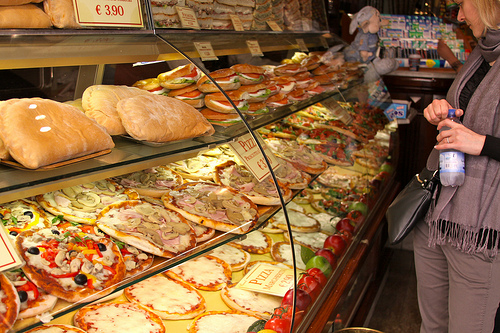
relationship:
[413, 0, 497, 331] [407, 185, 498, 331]
woman wearing gray pants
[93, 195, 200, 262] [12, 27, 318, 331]
pizza in a case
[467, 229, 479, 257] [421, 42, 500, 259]
fringe on scarf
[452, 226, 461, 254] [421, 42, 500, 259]
fringe on scarf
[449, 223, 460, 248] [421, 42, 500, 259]
fringe on scarf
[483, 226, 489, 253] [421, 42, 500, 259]
fringe on scarf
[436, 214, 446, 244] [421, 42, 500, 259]
fringe on scarf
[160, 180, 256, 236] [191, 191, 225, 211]
pizza with toppings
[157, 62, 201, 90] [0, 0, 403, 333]
sandwich in display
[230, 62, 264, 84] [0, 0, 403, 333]
sandwich in display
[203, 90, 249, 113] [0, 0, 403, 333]
sandwich in display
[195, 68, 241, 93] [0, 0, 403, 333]
sandwich in display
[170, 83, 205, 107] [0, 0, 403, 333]
sandwich in display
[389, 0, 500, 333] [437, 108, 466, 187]
woman holding bottle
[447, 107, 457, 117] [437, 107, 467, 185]
cap on bottle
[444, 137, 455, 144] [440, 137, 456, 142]
band around finger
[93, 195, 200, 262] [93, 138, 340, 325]
pizza behind glass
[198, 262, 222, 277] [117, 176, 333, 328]
cheese behind glass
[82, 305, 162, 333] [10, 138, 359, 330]
pizza behind glass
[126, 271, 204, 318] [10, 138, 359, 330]
pizza behind glass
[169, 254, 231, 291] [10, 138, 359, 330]
pizza behind glass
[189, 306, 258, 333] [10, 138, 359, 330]
pizza behind glass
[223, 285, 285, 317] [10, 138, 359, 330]
pizza behind glass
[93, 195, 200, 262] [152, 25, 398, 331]
pizza behind glass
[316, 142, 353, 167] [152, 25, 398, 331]
cheese pizza behind glass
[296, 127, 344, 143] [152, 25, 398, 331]
cheese pizza behind glass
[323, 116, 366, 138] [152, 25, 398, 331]
cheese pizza behind glass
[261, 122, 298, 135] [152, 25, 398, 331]
cheese pizza behind glass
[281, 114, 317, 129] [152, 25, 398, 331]
cheese pizza behind glass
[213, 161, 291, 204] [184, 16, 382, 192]
pizza behind glass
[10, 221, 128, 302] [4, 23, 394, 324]
pizza in shelf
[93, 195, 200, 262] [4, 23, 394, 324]
pizza in shelf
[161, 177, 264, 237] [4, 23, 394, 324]
pizza in shelf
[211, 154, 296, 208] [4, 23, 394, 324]
pizza in shelf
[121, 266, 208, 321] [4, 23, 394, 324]
pizza in shelf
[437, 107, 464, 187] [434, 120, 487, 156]
bottle in hand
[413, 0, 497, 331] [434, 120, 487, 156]
woman has hand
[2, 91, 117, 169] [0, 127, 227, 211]
calzone on shelf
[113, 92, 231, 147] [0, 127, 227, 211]
calzone on shelf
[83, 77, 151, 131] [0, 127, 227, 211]
calzone on shelf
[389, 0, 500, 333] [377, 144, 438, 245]
woman has purse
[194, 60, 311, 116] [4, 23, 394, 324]
sandwiches on shelf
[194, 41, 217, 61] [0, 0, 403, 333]
sign on display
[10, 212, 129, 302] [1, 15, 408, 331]
pizza in case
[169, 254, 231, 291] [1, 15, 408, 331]
pizza in case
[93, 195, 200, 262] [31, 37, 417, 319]
pizza in case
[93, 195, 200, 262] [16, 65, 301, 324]
pizza in case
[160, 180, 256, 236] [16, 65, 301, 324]
pizza in case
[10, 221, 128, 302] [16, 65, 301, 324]
pizza in case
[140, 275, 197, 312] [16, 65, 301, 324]
pizza in case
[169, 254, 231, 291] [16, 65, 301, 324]
pizza in case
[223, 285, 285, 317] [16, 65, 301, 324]
pizza in case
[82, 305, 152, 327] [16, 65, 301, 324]
pizza in case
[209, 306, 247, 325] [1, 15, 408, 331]
pizza in case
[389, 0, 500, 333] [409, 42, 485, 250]
woman wearing scarf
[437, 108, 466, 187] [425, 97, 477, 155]
bottle in hands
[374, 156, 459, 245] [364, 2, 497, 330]
purse carried by woman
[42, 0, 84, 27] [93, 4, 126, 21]
product has price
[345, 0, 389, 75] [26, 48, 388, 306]
doll on case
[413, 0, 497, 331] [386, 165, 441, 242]
woman wearing purse